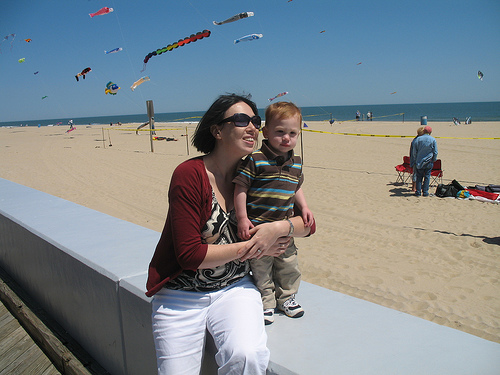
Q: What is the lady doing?
A: Holding a child.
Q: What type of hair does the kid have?
A: Red hair.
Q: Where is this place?
A: The beach.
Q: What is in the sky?
A: Kites.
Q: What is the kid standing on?
A: A wide concrete wall.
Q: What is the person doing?
A: Sitting on concrete.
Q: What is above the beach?
A: Kites flying.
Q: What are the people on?
A: Concrete wall.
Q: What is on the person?
A: White pants.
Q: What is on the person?
A: Dressed at the beach.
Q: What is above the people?
A: Kites.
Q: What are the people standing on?
A: Sand.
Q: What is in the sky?
A: Kites.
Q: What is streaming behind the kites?
A: Kite tails.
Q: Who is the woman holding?
A: Toddler.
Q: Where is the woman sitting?
A: Stone ledge.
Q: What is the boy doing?
A: Standing on stone ledge.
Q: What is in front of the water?
A: Sand.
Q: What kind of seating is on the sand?
A: Folding lawn chairs.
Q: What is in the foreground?
A: Mother and child.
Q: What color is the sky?
A: Blue.